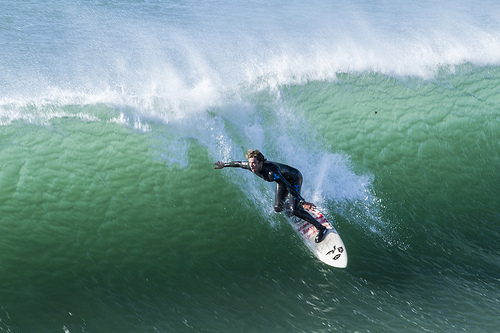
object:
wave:
[0, 47, 500, 330]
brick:
[244, 156, 259, 171]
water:
[1, 51, 171, 325]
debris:
[374, 109, 377, 114]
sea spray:
[6, 14, 498, 107]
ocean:
[0, 0, 500, 333]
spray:
[38, 11, 458, 63]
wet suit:
[233, 154, 325, 225]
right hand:
[214, 157, 231, 187]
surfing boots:
[299, 211, 336, 251]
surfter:
[191, 129, 341, 246]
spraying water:
[104, 35, 374, 214]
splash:
[122, 90, 219, 195]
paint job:
[323, 242, 345, 266]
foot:
[298, 223, 333, 255]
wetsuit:
[223, 160, 324, 235]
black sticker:
[333, 251, 342, 261]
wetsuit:
[230, 153, 335, 241]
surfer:
[206, 134, 361, 265]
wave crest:
[0, 0, 497, 180]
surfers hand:
[206, 154, 237, 179]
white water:
[0, 45, 498, 108]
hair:
[244, 147, 266, 162]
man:
[212, 144, 333, 244]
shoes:
[315, 227, 330, 246]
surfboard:
[281, 197, 349, 269]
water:
[2, 267, 498, 330]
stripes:
[291, 198, 337, 238]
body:
[315, 85, 499, 193]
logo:
[268, 168, 282, 183]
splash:
[187, 42, 377, 102]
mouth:
[249, 167, 259, 172]